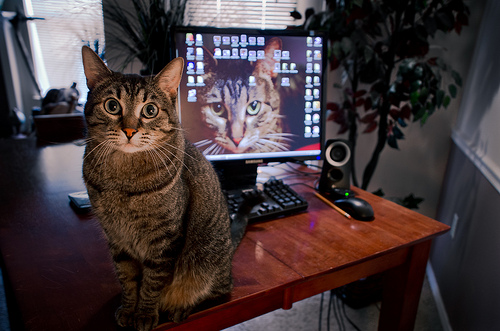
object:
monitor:
[182, 29, 322, 161]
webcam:
[317, 166, 343, 196]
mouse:
[332, 195, 376, 225]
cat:
[79, 46, 234, 331]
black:
[192, 29, 241, 35]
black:
[227, 190, 285, 215]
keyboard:
[225, 177, 310, 226]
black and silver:
[321, 140, 353, 187]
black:
[352, 200, 371, 216]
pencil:
[311, 190, 352, 220]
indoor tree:
[287, 1, 474, 191]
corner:
[324, 1, 499, 263]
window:
[183, 0, 296, 32]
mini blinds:
[182, 0, 297, 31]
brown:
[267, 215, 349, 262]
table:
[0, 139, 452, 330]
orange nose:
[117, 129, 137, 137]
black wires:
[315, 295, 324, 331]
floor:
[222, 281, 440, 331]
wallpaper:
[174, 28, 323, 160]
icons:
[279, 75, 291, 89]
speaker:
[317, 138, 355, 199]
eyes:
[138, 102, 163, 121]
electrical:
[447, 213, 459, 242]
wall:
[427, 16, 499, 329]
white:
[118, 145, 142, 152]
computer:
[163, 27, 329, 233]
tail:
[227, 194, 264, 254]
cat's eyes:
[102, 94, 126, 120]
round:
[138, 103, 162, 119]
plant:
[306, 0, 464, 192]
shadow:
[0, 144, 45, 292]